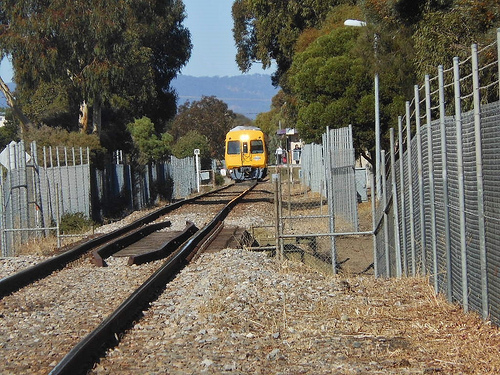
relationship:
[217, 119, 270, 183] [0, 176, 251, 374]
bus going down tracks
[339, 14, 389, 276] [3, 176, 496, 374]
light in street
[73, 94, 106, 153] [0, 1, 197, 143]
trunk of trees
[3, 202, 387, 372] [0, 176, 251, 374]
rocks along tracks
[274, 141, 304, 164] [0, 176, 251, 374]
people standing on tracks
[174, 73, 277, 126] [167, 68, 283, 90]
hill in distance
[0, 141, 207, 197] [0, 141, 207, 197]
fence on other fence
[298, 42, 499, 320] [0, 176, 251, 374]
fence near track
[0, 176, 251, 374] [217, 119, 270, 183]
tracks of train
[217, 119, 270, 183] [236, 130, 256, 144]
train has white light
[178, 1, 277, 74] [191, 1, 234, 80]
sky has no clouds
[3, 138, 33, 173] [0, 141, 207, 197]
diamond behind fence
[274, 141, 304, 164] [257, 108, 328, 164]
people standing in distance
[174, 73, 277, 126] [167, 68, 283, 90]
mountain in distance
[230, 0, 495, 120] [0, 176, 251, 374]
trees on side tracks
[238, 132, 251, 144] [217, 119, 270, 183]
light front of train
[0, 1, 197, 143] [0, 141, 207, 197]
tree along fence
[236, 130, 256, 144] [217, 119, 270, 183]
headlight on train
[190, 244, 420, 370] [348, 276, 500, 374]
rocks in grass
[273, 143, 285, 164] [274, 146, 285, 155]
man in white shirt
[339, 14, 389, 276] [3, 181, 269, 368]
pole on side of tracks